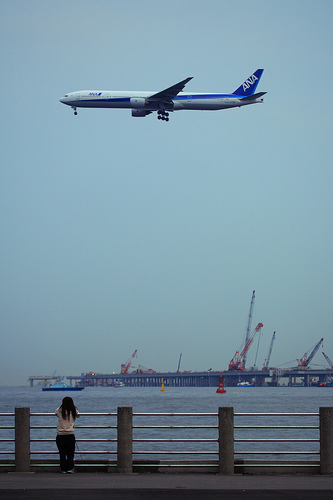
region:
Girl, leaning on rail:
[52, 389, 88, 483]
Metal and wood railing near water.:
[117, 406, 330, 470]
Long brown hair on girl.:
[60, 395, 82, 425]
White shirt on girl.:
[55, 405, 84, 438]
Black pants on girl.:
[55, 433, 79, 469]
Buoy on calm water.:
[216, 372, 225, 397]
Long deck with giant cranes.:
[72, 323, 331, 383]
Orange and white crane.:
[227, 322, 264, 373]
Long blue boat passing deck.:
[44, 374, 88, 393]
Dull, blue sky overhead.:
[45, 306, 227, 357]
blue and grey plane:
[59, 66, 277, 121]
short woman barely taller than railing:
[51, 394, 87, 477]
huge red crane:
[228, 322, 267, 372]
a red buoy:
[213, 367, 232, 397]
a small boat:
[41, 376, 88, 392]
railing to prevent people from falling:
[1, 404, 332, 482]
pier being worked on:
[22, 360, 332, 389]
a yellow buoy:
[158, 377, 167, 393]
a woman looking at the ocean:
[34, 371, 102, 477]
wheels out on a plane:
[103, 76, 184, 125]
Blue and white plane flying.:
[52, 51, 276, 138]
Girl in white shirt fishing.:
[51, 391, 77, 472]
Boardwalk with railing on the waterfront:
[0, 393, 328, 494]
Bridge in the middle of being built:
[22, 354, 327, 386]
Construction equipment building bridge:
[224, 285, 280, 363]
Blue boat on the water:
[27, 373, 102, 393]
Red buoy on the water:
[212, 366, 225, 392]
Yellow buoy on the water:
[151, 375, 169, 395]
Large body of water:
[0, 380, 328, 451]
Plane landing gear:
[63, 107, 178, 125]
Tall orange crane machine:
[226, 317, 266, 374]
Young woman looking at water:
[49, 391, 81, 479]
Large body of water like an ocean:
[2, 374, 327, 458]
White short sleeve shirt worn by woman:
[54, 404, 82, 433]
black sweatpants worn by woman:
[52, 429, 80, 471]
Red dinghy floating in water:
[212, 371, 228, 397]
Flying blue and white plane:
[62, 65, 267, 123]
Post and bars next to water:
[80, 408, 332, 473]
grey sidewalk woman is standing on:
[2, 469, 321, 498]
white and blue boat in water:
[40, 378, 85, 395]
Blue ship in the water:
[40, 378, 83, 391]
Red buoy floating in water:
[211, 368, 226, 391]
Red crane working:
[116, 347, 143, 373]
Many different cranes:
[224, 288, 326, 370]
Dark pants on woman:
[54, 434, 78, 471]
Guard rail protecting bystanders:
[1, 405, 332, 474]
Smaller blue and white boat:
[234, 378, 254, 386]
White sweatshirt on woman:
[53, 408, 76, 433]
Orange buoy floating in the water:
[156, 381, 165, 391]